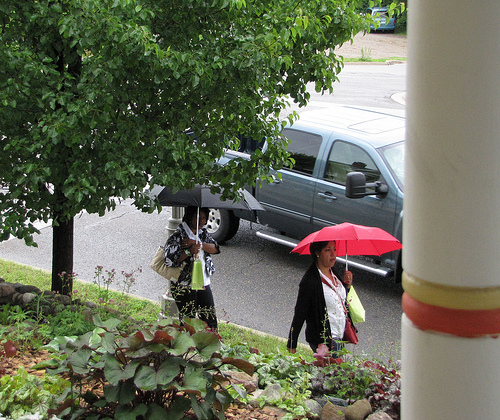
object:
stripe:
[400, 263, 500, 342]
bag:
[346, 285, 365, 323]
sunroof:
[347, 115, 406, 135]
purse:
[320, 275, 358, 345]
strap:
[319, 274, 347, 316]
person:
[287, 240, 366, 361]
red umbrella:
[290, 221, 403, 283]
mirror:
[346, 172, 388, 199]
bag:
[149, 246, 186, 283]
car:
[182, 105, 405, 284]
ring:
[401, 270, 499, 338]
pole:
[398, 0, 499, 419]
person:
[164, 206, 218, 335]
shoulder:
[305, 266, 317, 279]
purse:
[190, 260, 206, 290]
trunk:
[50, 195, 73, 297]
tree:
[0, 0, 373, 306]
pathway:
[10, 162, 401, 369]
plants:
[1, 307, 401, 419]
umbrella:
[139, 180, 268, 213]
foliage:
[96, 340, 209, 384]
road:
[0, 61, 403, 369]